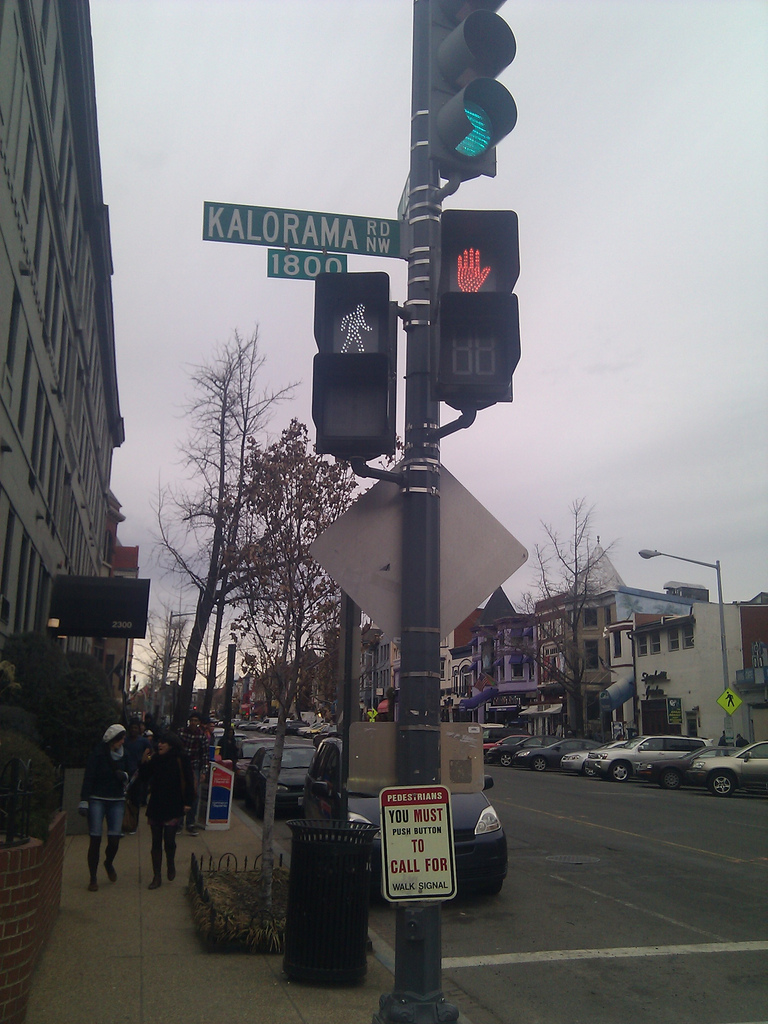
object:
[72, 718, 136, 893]
woman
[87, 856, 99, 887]
boots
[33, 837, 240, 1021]
sidewalk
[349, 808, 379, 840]
headlight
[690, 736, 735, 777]
car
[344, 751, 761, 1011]
street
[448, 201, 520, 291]
traffic light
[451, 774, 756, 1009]
road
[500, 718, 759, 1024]
grey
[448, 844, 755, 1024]
road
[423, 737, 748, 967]
road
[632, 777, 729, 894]
lines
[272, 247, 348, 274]
sign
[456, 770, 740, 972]
grey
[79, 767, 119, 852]
walking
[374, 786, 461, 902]
sign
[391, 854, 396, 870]
lettering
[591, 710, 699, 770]
suv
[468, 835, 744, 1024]
street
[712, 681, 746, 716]
sign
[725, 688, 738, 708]
person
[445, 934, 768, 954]
line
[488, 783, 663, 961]
street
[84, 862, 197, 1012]
sidewalk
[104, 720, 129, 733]
hat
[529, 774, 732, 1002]
street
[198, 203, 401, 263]
street sign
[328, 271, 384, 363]
traffic signal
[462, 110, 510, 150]
light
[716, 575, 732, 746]
pole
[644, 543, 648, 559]
street light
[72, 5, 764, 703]
skies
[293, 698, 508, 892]
car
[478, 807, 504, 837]
headlight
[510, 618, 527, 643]
window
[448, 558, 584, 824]
building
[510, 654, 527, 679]
window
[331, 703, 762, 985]
street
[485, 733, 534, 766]
car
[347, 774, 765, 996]
street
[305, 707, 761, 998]
street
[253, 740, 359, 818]
car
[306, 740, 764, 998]
street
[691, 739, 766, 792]
car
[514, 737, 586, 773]
car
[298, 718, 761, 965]
street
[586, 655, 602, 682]
window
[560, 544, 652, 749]
building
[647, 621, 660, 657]
window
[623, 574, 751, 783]
building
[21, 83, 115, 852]
building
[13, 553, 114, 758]
wall